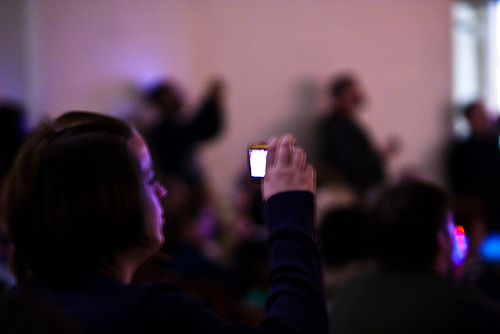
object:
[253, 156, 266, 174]
light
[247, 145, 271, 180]
camera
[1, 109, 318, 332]
lady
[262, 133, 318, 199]
hand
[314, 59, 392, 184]
person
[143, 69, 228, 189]
another person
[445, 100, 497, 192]
blurry person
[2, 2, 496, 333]
picture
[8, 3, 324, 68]
wall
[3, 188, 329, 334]
sweater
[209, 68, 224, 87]
cell phone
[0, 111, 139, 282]
hair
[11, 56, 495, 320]
people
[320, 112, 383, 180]
jacket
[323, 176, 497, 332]
man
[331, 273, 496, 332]
shirt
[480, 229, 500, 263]
blue light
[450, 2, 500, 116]
window light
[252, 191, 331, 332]
sleeve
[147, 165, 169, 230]
glow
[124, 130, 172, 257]
face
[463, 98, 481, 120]
brown hair